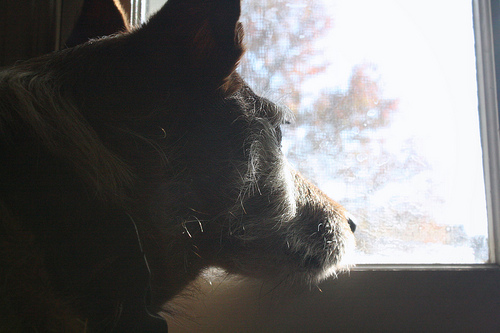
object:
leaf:
[296, 10, 314, 29]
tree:
[235, 0, 394, 240]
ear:
[132, 0, 249, 100]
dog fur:
[21, 16, 358, 303]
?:
[394, 182, 401, 192]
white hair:
[6, 60, 135, 205]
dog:
[2, 1, 384, 330]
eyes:
[273, 109, 307, 173]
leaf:
[290, 31, 305, 44]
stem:
[256, 17, 381, 111]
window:
[277, 17, 472, 223]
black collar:
[134, 112, 206, 269]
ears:
[139, 0, 244, 77]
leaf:
[319, 87, 380, 142]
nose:
[347, 213, 357, 234]